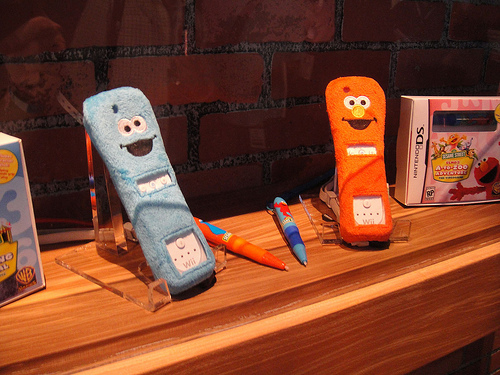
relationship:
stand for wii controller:
[59, 123, 227, 312] [80, 84, 213, 291]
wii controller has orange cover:
[345, 142, 382, 228] [324, 73, 393, 242]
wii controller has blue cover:
[80, 84, 213, 291] [81, 85, 216, 295]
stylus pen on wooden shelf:
[271, 194, 308, 269] [0, 203, 498, 374]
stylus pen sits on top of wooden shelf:
[271, 194, 308, 269] [0, 203, 498, 374]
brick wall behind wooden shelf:
[2, 1, 498, 223] [0, 203, 498, 374]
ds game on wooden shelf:
[394, 93, 499, 205] [0, 203, 498, 374]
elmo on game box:
[446, 157, 498, 197] [0, 128, 48, 313]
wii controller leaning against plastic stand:
[80, 84, 213, 291] [55, 128, 227, 315]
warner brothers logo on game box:
[14, 265, 36, 284] [0, 128, 48, 313]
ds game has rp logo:
[394, 93, 499, 205] [421, 183, 439, 201]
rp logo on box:
[421, 183, 439, 201] [393, 94, 498, 204]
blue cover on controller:
[81, 85, 216, 295] [136, 168, 208, 282]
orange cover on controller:
[324, 73, 393, 242] [343, 142, 387, 229]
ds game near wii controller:
[394, 93, 499, 205] [323, 76, 394, 243]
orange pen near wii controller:
[191, 216, 292, 271] [80, 84, 213, 291]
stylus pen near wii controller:
[271, 194, 308, 269] [323, 76, 394, 243]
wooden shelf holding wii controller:
[0, 203, 498, 374] [80, 84, 213, 291]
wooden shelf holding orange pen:
[0, 203, 498, 374] [191, 216, 292, 271]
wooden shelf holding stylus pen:
[0, 203, 498, 374] [271, 194, 308, 269]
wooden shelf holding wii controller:
[0, 203, 498, 374] [323, 76, 394, 243]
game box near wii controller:
[0, 128, 48, 313] [80, 84, 213, 291]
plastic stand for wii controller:
[55, 128, 227, 315] [80, 84, 213, 291]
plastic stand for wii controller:
[55, 128, 227, 315] [323, 76, 394, 243]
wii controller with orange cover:
[323, 76, 394, 243] [324, 73, 393, 242]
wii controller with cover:
[80, 84, 213, 291] [108, 137, 198, 284]